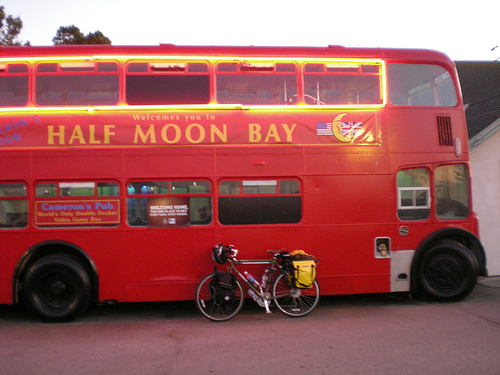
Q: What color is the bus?
A: Red.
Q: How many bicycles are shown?
A: One.